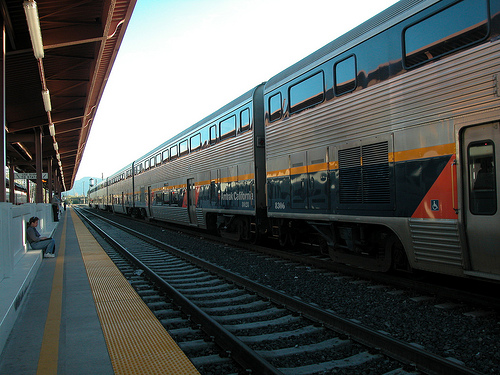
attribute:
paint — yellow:
[56, 192, 206, 374]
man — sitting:
[21, 215, 56, 258]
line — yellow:
[46, 232, 67, 368]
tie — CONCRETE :
[152, 290, 258, 310]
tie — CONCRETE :
[159, 304, 286, 326]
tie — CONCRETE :
[170, 312, 305, 337]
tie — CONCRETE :
[176, 322, 322, 349]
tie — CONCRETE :
[189, 335, 349, 367]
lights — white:
[25, 3, 46, 61]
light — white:
[38, 88, 55, 112]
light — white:
[47, 123, 58, 135]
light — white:
[57, 153, 61, 164]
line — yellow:
[67, 202, 202, 374]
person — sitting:
[27, 217, 55, 259]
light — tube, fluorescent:
[25, 0, 45, 57]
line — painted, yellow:
[47, 245, 67, 367]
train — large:
[74, 3, 498, 278]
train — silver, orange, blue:
[133, 117, 475, 264]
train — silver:
[118, 53, 498, 256]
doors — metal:
[442, 115, 496, 277]